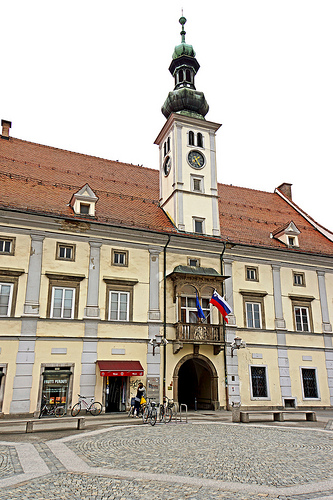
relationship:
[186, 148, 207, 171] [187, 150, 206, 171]
clock of clock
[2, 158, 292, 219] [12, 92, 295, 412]
roof of building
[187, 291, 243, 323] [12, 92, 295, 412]
flags on building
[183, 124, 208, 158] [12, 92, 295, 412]
windows on building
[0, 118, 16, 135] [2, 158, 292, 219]
chimney on roof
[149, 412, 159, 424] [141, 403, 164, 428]
wheel of bicycle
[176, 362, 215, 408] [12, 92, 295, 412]
tunnel in building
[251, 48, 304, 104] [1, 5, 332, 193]
clouds in sky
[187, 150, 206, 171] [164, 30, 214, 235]
clock on tower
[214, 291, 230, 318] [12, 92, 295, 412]
flag on building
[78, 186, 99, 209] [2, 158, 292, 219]
window on roof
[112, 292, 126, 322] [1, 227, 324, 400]
window in wall